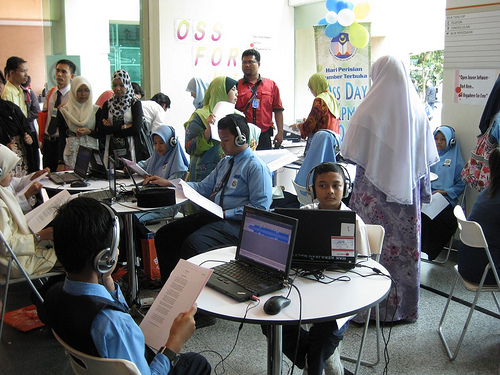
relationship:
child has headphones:
[301, 161, 375, 254] [314, 157, 352, 194]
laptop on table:
[215, 212, 307, 315] [197, 226, 397, 328]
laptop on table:
[282, 210, 365, 266] [197, 226, 397, 328]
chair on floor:
[351, 227, 390, 260] [394, 295, 482, 370]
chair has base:
[351, 227, 390, 260] [329, 341, 381, 370]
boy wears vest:
[36, 217, 179, 362] [22, 286, 122, 346]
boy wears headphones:
[36, 217, 179, 362] [62, 202, 125, 268]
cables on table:
[279, 240, 361, 284] [197, 226, 397, 328]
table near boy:
[197, 226, 397, 328] [36, 217, 179, 362]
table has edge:
[197, 226, 397, 328] [316, 275, 398, 302]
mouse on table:
[245, 287, 294, 309] [197, 226, 397, 328]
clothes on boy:
[66, 280, 233, 372] [36, 217, 179, 362]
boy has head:
[36, 217, 179, 362] [60, 195, 110, 271]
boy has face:
[301, 161, 375, 254] [310, 170, 348, 197]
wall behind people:
[164, 3, 295, 129] [4, 32, 497, 356]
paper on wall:
[454, 69, 492, 100] [443, 9, 489, 151]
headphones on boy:
[314, 157, 352, 194] [301, 161, 375, 254]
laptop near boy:
[215, 212, 307, 315] [36, 217, 179, 362]